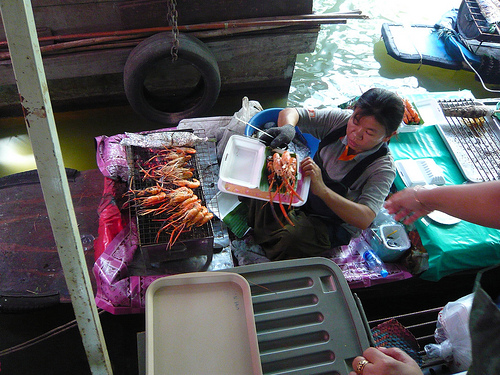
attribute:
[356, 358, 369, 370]
band — gold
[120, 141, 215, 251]
shrimp — large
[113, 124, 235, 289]
seafood — fresh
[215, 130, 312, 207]
container — styrofoam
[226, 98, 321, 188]
bucket — plastic, blue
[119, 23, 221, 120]
tire — black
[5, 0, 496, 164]
river — dirty, green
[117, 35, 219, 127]
tire — black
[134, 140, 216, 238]
shrimp — few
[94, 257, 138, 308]
bandanna print — purple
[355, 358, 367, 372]
ring — gold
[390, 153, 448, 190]
styrofoam container — white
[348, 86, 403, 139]
hair — black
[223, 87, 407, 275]
woman — sitting down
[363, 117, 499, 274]
tarp — pale, green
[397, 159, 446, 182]
box — white, togo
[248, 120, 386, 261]
apron — black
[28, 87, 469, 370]
dock — riverside